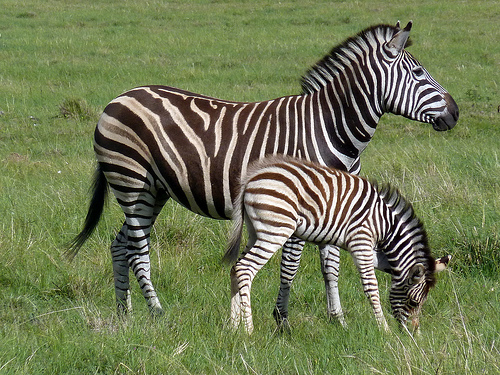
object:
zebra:
[59, 19, 460, 335]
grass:
[0, 0, 500, 375]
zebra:
[219, 153, 452, 336]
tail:
[221, 176, 253, 267]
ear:
[381, 20, 413, 64]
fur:
[218, 153, 452, 337]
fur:
[58, 19, 462, 334]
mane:
[298, 23, 414, 96]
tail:
[57, 162, 110, 264]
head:
[379, 19, 460, 132]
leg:
[230, 224, 298, 329]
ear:
[408, 263, 425, 285]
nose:
[444, 93, 460, 122]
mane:
[370, 177, 438, 288]